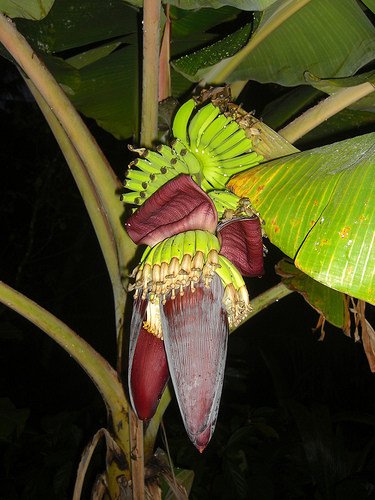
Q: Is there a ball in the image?
A: No, there are no balls.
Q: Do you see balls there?
A: No, there are no balls.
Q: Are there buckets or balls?
A: No, there are no balls or buckets.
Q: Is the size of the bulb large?
A: Yes, the bulb is large.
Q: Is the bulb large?
A: Yes, the bulb is large.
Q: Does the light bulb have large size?
A: Yes, the light bulb is large.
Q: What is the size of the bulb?
A: The bulb is large.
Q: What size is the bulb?
A: The bulb is large.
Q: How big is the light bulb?
A: The light bulb is large.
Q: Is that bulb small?
A: No, the bulb is large.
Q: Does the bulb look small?
A: No, the bulb is large.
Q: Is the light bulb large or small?
A: The light bulb is large.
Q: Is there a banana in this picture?
A: Yes, there is a banana.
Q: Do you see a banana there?
A: Yes, there is a banana.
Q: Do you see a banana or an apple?
A: Yes, there is a banana.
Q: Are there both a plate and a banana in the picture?
A: No, there is a banana but no plates.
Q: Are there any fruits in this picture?
A: Yes, there is a fruit.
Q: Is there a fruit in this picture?
A: Yes, there is a fruit.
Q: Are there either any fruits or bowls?
A: Yes, there is a fruit.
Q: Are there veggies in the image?
A: No, there are no veggies.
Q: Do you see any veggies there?
A: No, there are no veggies.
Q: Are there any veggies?
A: No, there are no veggies.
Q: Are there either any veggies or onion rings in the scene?
A: No, there are no veggies or onion rings.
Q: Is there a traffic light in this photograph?
A: No, there are no traffic lights.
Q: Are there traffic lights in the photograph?
A: No, there are no traffic lights.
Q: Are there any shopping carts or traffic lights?
A: No, there are no traffic lights or shopping carts.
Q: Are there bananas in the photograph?
A: Yes, there is a banana.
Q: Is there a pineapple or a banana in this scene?
A: Yes, there is a banana.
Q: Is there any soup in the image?
A: No, there is no soup.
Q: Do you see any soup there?
A: No, there is no soup.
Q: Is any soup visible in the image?
A: No, there is no soup.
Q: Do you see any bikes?
A: No, there are no bikes.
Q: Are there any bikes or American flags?
A: No, there are no bikes or American flags.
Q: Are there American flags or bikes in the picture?
A: No, there are no bikes or American flags.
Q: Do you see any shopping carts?
A: No, there are no shopping carts.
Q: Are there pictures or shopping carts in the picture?
A: No, there are no shopping carts or pictures.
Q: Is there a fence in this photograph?
A: No, there are no fences.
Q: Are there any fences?
A: No, there are no fences.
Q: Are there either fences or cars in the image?
A: No, there are no fences or cars.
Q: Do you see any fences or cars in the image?
A: No, there are no fences or cars.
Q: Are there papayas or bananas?
A: Yes, there are bananas.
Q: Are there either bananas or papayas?
A: Yes, there are bananas.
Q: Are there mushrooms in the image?
A: No, there are no mushrooms.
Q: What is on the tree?
A: The bananas are on the tree.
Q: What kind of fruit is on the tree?
A: The fruits are bananas.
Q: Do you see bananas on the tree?
A: Yes, there are bananas on the tree.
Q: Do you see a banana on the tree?
A: Yes, there are bananas on the tree.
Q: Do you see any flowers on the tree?
A: No, there are bananas on the tree.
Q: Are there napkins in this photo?
A: No, there are no napkins.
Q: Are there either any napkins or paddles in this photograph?
A: No, there are no napkins or paddles.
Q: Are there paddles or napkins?
A: No, there are no napkins or paddles.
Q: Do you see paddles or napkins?
A: No, there are no napkins or paddles.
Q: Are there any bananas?
A: Yes, there is a banana.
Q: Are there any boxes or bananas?
A: Yes, there is a banana.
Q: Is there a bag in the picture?
A: No, there are no bags.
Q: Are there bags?
A: No, there are no bags.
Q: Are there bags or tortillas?
A: No, there are no bags or tortillas.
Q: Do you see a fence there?
A: No, there are no fences.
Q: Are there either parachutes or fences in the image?
A: No, there are no fences or parachutes.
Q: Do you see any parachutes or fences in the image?
A: No, there are no fences or parachutes.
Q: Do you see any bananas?
A: Yes, there are bananas.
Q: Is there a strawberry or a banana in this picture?
A: Yes, there are bananas.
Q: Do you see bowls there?
A: No, there are no bowls.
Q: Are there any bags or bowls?
A: No, there are no bowls or bags.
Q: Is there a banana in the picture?
A: Yes, there is a banana.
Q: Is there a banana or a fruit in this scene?
A: Yes, there is a banana.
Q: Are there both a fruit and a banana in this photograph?
A: Yes, there are both a banana and a fruit.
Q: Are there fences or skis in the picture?
A: No, there are no fences or skis.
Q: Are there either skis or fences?
A: No, there are no fences or skis.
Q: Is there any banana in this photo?
A: Yes, there is a banana.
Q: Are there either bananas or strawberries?
A: Yes, there is a banana.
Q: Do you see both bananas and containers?
A: No, there is a banana but no containers.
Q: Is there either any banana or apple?
A: Yes, there is a banana.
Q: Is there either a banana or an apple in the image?
A: Yes, there is a banana.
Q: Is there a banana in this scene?
A: Yes, there is a banana.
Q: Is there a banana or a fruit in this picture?
A: Yes, there is a banana.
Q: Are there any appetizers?
A: No, there are no appetizers.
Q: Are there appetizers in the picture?
A: No, there are no appetizers.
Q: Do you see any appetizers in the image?
A: No, there are no appetizers.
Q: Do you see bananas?
A: Yes, there is a banana.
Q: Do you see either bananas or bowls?
A: Yes, there is a banana.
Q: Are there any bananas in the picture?
A: Yes, there is a banana.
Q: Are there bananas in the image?
A: Yes, there is a banana.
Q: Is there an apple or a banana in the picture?
A: Yes, there is a banana.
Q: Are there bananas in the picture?
A: Yes, there is a banana.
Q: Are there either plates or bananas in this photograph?
A: Yes, there is a banana.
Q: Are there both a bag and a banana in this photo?
A: No, there is a banana but no bags.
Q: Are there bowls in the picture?
A: No, there are no bowls.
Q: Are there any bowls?
A: No, there are no bowls.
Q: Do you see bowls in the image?
A: No, there are no bowls.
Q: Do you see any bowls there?
A: No, there are no bowls.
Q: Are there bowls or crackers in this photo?
A: No, there are no bowls or crackers.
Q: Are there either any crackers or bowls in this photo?
A: No, there are no bowls or crackers.